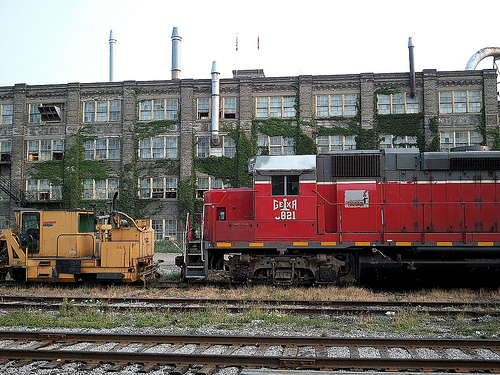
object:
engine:
[202, 190, 252, 242]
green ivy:
[26, 85, 500, 228]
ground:
[321, 324, 454, 368]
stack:
[171, 27, 182, 80]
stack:
[109, 30, 117, 82]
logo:
[273, 199, 297, 220]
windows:
[136, 178, 181, 198]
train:
[183, 148, 499, 285]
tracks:
[1, 295, 500, 374]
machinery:
[0, 208, 160, 288]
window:
[271, 175, 285, 196]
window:
[287, 175, 299, 195]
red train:
[175, 146, 499, 287]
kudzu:
[29, 114, 499, 229]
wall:
[0, 78, 498, 252]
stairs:
[184, 213, 204, 279]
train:
[0, 210, 156, 289]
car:
[176, 148, 499, 286]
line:
[215, 241, 494, 246]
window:
[222, 98, 235, 120]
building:
[0, 69, 499, 252]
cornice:
[0, 69, 497, 98]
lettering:
[273, 198, 296, 219]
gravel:
[1, 298, 499, 375]